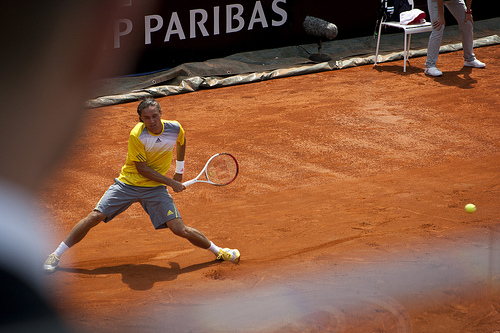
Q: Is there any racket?
A: Yes, there is a racket.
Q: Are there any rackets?
A: Yes, there is a racket.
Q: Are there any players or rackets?
A: Yes, there is a racket.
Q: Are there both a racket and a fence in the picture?
A: No, there is a racket but no fences.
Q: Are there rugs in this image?
A: No, there are no rugs.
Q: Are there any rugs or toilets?
A: No, there are no rugs or toilets.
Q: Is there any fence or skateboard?
A: No, there are no fences or skateboards.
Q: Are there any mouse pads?
A: No, there are no mouse pads.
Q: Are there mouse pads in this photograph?
A: No, there are no mouse pads.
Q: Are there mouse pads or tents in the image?
A: No, there are no mouse pads or tents.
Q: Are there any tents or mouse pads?
A: No, there are no mouse pads or tents.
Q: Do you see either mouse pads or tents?
A: No, there are no mouse pads or tents.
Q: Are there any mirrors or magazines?
A: No, there are no mirrors or magazines.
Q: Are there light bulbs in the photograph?
A: No, there are no light bulbs.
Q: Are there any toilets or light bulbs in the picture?
A: No, there are no light bulbs or toilets.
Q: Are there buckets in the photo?
A: No, there are no buckets.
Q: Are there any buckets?
A: No, there are no buckets.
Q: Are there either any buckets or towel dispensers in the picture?
A: No, there are no buckets or towel dispensers.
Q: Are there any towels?
A: Yes, there is a towel.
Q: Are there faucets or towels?
A: Yes, there is a towel.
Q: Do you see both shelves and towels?
A: No, there is a towel but no shelves.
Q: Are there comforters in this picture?
A: No, there are no comforters.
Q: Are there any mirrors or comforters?
A: No, there are no comforters or mirrors.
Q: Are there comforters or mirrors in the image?
A: No, there are no comforters or mirrors.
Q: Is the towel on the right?
A: Yes, the towel is on the right of the image.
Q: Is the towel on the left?
A: No, the towel is on the right of the image.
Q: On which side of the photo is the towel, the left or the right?
A: The towel is on the right of the image.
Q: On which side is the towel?
A: The towel is on the right of the image.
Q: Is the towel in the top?
A: Yes, the towel is in the top of the image.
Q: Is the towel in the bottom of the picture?
A: No, the towel is in the top of the image.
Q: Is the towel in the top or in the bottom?
A: The towel is in the top of the image.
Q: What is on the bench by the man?
A: The towel is on the bench.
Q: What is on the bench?
A: The towel is on the bench.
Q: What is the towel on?
A: The towel is on the bench.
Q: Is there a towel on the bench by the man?
A: Yes, there is a towel on the bench.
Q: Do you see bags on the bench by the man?
A: No, there is a towel on the bench.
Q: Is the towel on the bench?
A: Yes, the towel is on the bench.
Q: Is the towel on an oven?
A: No, the towel is on the bench.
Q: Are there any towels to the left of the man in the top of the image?
A: Yes, there is a towel to the left of the man.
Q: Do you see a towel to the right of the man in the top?
A: No, the towel is to the left of the man.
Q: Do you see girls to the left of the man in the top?
A: No, there is a towel to the left of the man.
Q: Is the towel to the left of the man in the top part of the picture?
A: Yes, the towel is to the left of the man.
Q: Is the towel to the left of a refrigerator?
A: No, the towel is to the left of the man.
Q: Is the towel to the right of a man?
A: No, the towel is to the left of a man.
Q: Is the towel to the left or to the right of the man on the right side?
A: The towel is to the left of the man.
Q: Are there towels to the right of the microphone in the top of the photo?
A: Yes, there is a towel to the right of the microphone.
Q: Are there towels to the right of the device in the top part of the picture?
A: Yes, there is a towel to the right of the microphone.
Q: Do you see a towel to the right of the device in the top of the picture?
A: Yes, there is a towel to the right of the microphone.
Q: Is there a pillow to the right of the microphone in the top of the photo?
A: No, there is a towel to the right of the microphone.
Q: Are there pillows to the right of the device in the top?
A: No, there is a towel to the right of the microphone.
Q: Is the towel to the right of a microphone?
A: Yes, the towel is to the right of a microphone.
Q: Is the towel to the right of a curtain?
A: No, the towel is to the right of a microphone.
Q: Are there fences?
A: No, there are no fences.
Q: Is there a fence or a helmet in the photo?
A: No, there are no fences or helmets.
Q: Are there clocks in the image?
A: No, there are no clocks.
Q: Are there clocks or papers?
A: No, there are no clocks or papers.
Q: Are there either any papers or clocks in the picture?
A: No, there are no clocks or papers.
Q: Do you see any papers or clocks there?
A: No, there are no clocks or papers.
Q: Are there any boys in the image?
A: No, there are no boys.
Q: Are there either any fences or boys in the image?
A: No, there are no boys or fences.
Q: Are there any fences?
A: No, there are no fences.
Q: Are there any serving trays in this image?
A: No, there are no serving trays.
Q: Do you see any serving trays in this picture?
A: No, there are no serving trays.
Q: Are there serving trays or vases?
A: No, there are no serving trays or vases.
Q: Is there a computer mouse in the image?
A: No, there are no computer mice.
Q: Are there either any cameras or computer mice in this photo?
A: No, there are no computer mice or cameras.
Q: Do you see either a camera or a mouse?
A: No, there are no computer mice or cameras.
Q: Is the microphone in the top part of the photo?
A: Yes, the microphone is in the top of the image.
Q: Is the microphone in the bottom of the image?
A: No, the microphone is in the top of the image.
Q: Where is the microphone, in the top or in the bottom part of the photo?
A: The microphone is in the top of the image.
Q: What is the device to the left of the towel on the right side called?
A: The device is a microphone.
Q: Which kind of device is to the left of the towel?
A: The device is a microphone.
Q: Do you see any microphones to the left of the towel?
A: Yes, there is a microphone to the left of the towel.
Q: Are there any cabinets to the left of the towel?
A: No, there is a microphone to the left of the towel.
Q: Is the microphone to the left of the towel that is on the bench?
A: Yes, the microphone is to the left of the towel.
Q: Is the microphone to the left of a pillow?
A: No, the microphone is to the left of the towel.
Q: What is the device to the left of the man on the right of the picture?
A: The device is a microphone.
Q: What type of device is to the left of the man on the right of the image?
A: The device is a microphone.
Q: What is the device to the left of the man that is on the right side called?
A: The device is a microphone.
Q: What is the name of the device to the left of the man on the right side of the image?
A: The device is a microphone.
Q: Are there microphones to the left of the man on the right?
A: Yes, there is a microphone to the left of the man.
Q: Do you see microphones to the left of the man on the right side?
A: Yes, there is a microphone to the left of the man.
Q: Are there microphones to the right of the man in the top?
A: No, the microphone is to the left of the man.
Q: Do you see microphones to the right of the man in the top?
A: No, the microphone is to the left of the man.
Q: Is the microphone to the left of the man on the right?
A: Yes, the microphone is to the left of the man.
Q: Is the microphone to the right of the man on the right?
A: No, the microphone is to the left of the man.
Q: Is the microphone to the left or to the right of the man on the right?
A: The microphone is to the left of the man.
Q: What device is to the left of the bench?
A: The device is a microphone.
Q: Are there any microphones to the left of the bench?
A: Yes, there is a microphone to the left of the bench.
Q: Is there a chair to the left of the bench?
A: No, there is a microphone to the left of the bench.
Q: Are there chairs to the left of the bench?
A: No, there is a microphone to the left of the bench.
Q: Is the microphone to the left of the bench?
A: Yes, the microphone is to the left of the bench.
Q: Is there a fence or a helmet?
A: No, there are no helmets or fences.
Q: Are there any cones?
A: No, there are no cones.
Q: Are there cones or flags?
A: No, there are no cones or flags.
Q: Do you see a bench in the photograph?
A: Yes, there is a bench.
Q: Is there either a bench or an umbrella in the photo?
A: Yes, there is a bench.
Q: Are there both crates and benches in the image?
A: No, there is a bench but no crates.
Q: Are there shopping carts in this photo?
A: No, there are no shopping carts.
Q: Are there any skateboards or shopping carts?
A: No, there are no shopping carts or skateboards.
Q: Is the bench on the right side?
A: Yes, the bench is on the right of the image.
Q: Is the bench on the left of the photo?
A: No, the bench is on the right of the image.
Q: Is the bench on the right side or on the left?
A: The bench is on the right of the image.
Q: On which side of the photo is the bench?
A: The bench is on the right of the image.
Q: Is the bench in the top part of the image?
A: Yes, the bench is in the top of the image.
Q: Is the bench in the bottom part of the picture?
A: No, the bench is in the top of the image.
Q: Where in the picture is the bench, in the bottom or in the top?
A: The bench is in the top of the image.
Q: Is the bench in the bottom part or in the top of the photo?
A: The bench is in the top of the image.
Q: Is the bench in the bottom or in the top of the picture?
A: The bench is in the top of the image.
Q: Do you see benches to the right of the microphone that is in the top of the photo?
A: Yes, there is a bench to the right of the microphone.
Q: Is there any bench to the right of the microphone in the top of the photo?
A: Yes, there is a bench to the right of the microphone.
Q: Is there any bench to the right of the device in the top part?
A: Yes, there is a bench to the right of the microphone.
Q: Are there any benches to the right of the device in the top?
A: Yes, there is a bench to the right of the microphone.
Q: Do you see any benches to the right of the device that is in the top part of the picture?
A: Yes, there is a bench to the right of the microphone.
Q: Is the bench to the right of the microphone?
A: Yes, the bench is to the right of the microphone.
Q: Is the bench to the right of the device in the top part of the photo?
A: Yes, the bench is to the right of the microphone.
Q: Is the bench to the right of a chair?
A: No, the bench is to the right of the microphone.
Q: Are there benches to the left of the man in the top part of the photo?
A: Yes, there is a bench to the left of the man.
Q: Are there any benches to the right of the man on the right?
A: No, the bench is to the left of the man.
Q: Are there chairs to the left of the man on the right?
A: No, there is a bench to the left of the man.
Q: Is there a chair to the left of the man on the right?
A: No, there is a bench to the left of the man.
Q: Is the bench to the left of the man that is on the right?
A: Yes, the bench is to the left of the man.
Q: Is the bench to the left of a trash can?
A: No, the bench is to the left of the man.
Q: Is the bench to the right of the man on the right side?
A: No, the bench is to the left of the man.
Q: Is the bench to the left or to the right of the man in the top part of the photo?
A: The bench is to the left of the man.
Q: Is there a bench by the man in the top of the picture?
A: Yes, there is a bench by the man.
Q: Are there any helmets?
A: No, there are no helmets.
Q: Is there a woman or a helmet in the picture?
A: No, there are no helmets or women.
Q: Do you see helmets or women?
A: No, there are no helmets or women.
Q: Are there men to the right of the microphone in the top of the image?
A: Yes, there is a man to the right of the microphone.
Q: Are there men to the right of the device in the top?
A: Yes, there is a man to the right of the microphone.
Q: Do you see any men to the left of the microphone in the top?
A: No, the man is to the right of the microphone.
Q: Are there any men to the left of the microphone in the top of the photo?
A: No, the man is to the right of the microphone.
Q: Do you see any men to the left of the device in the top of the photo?
A: No, the man is to the right of the microphone.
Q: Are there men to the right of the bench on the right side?
A: Yes, there is a man to the right of the bench.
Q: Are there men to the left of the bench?
A: No, the man is to the right of the bench.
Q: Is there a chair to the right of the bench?
A: No, there is a man to the right of the bench.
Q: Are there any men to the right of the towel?
A: Yes, there is a man to the right of the towel.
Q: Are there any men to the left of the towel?
A: No, the man is to the right of the towel.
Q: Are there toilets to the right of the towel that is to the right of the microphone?
A: No, there is a man to the right of the towel.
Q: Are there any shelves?
A: No, there are no shelves.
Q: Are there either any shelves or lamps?
A: No, there are no shelves or lamps.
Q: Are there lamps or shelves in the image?
A: No, there are no shelves or lamps.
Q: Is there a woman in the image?
A: No, there are no women.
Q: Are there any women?
A: No, there are no women.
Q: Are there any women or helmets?
A: No, there are no women or helmets.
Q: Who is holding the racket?
A: The man is holding the racket.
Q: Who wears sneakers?
A: The man wears sneakers.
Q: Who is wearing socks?
A: The man is wearing socks.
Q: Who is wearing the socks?
A: The man is wearing socks.